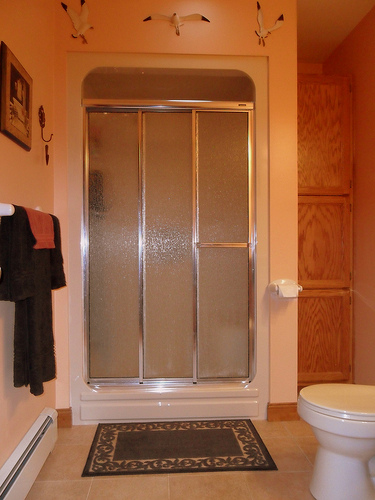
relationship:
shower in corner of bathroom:
[71, 64, 259, 395] [0, 1, 375, 498]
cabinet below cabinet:
[295, 189, 353, 289] [297, 56, 355, 190]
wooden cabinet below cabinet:
[298, 287, 352, 386] [295, 189, 353, 289]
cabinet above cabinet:
[301, 73, 350, 191] [295, 189, 353, 289]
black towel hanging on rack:
[0, 204, 65, 393] [0, 202, 15, 215]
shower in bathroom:
[71, 64, 259, 395] [0, 1, 375, 498]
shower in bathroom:
[71, 64, 259, 395] [6, 8, 372, 352]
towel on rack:
[24, 203, 57, 253] [0, 199, 62, 226]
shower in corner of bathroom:
[71, 64, 259, 395] [49, 22, 373, 483]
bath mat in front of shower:
[82, 417, 278, 478] [58, 71, 273, 369]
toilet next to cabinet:
[293, 378, 374, 499] [288, 60, 360, 385]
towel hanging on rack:
[24, 203, 57, 253] [0, 203, 15, 217]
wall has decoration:
[101, 10, 129, 43] [137, 5, 212, 35]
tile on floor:
[86, 468, 310, 497] [253, 467, 291, 492]